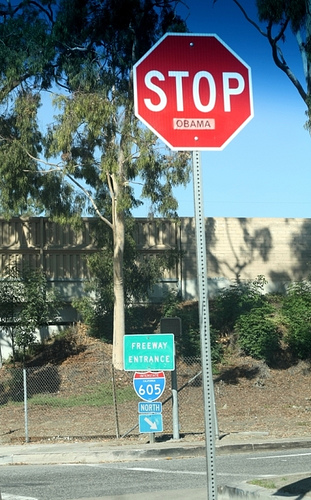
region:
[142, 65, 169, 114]
white letter on a sign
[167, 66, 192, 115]
white letter on a sign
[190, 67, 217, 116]
white letter on a sign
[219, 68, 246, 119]
white letter on a sign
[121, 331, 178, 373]
green sign on roadside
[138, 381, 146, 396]
white letter on a sign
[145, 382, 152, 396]
white letter on a sign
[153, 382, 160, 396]
white letter on a sign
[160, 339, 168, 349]
white letter on a sign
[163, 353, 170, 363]
white letter on a sign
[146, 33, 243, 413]
A stop sign at the cornor.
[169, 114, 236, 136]
Obama sticker on stop sign.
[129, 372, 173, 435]
North 605 sign attached to fence.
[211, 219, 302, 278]
A yellow brick wall on top of hill.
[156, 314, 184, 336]
A crosswalk light behind sign.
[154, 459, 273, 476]
A road made of concrete.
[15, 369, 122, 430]
A chain link fence around hill.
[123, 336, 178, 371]
Green sign reading Freeway Entrance.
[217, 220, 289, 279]
Shadows of the trees on wall.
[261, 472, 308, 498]
A shadow of the stop sign on grass.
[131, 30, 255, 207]
a red octagon sign is on a pole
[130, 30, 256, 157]
the sign has white lettering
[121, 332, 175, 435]
directional signs are beside the road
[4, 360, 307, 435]
a chain link fence is near a sidewalk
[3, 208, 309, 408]
a building is near the intersection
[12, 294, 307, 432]
a mound is in front of the building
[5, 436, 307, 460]
a cement curb is next to the road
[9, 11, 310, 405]
tall trees are on the hill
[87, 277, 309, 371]
green shrubs are on the hill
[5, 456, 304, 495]
the intersection is asphalt with white lines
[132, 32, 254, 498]
A stop sign attached to a metal pole.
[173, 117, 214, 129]
A sticker attached to the stop sign.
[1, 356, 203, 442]
An incomplete chain-link fence.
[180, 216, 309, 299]
A light colored brick wall.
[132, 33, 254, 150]
A stop sign with a political message on it.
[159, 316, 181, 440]
An electric crosswalk sign.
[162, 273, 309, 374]
Shrubs planted near the brick wall.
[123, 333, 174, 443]
Four road signs attached to one pole.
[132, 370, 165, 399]
A sign giving the name of the interstate.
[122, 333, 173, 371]
A green informational sign.